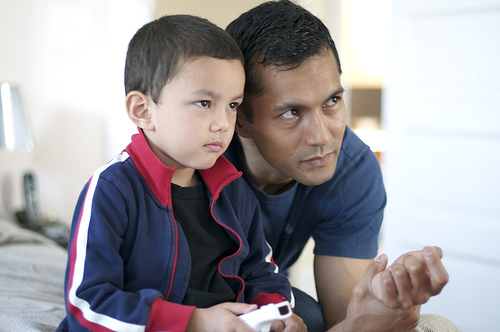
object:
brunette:
[146, 27, 228, 53]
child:
[54, 14, 314, 332]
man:
[218, 3, 456, 332]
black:
[255, 11, 297, 37]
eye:
[280, 107, 300, 123]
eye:
[190, 95, 213, 110]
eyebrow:
[191, 89, 224, 99]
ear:
[127, 88, 158, 134]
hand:
[369, 240, 446, 311]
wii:
[235, 300, 294, 331]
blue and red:
[122, 129, 171, 222]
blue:
[333, 189, 376, 220]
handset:
[13, 207, 78, 246]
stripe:
[73, 149, 151, 332]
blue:
[105, 211, 136, 249]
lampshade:
[0, 83, 35, 152]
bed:
[0, 217, 74, 325]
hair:
[219, 0, 343, 72]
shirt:
[222, 124, 389, 273]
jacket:
[58, 128, 299, 332]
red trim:
[126, 127, 176, 207]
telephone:
[12, 170, 73, 248]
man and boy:
[54, 0, 455, 332]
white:
[258, 313, 268, 320]